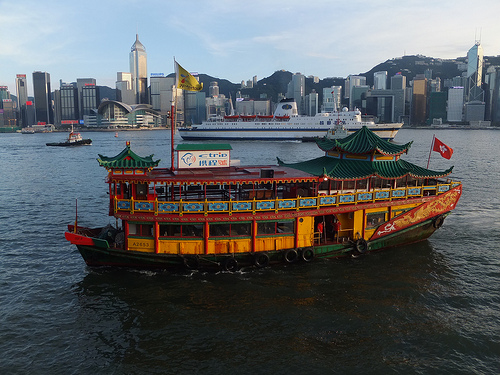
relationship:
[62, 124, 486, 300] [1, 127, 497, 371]
boat on river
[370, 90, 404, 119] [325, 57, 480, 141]
wall supporting building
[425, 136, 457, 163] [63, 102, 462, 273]
flag on boat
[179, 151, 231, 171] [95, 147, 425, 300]
advertisement on boat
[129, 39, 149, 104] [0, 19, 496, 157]
building in city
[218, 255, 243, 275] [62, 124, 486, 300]
tire on boat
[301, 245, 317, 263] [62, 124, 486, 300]
tire on boat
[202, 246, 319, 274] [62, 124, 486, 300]
row on boat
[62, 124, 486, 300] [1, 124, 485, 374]
boat in water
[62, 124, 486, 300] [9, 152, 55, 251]
boat on water